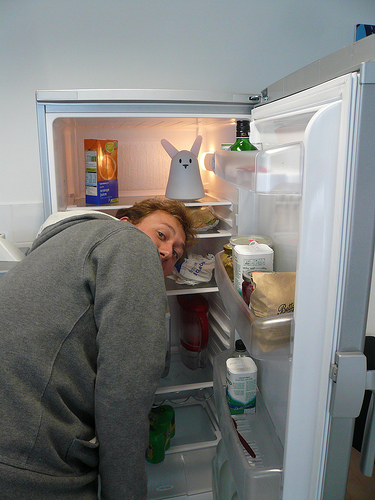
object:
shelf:
[62, 186, 234, 297]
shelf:
[138, 350, 285, 500]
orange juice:
[82, 136, 119, 205]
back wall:
[63, 124, 218, 406]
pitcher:
[172, 292, 210, 370]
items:
[215, 248, 295, 363]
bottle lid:
[236, 119, 251, 137]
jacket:
[0, 207, 172, 500]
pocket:
[66, 433, 100, 482]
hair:
[115, 194, 205, 268]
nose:
[158, 241, 173, 263]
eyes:
[154, 228, 168, 245]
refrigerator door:
[211, 30, 374, 500]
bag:
[247, 269, 296, 353]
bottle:
[228, 116, 259, 155]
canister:
[176, 293, 211, 370]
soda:
[143, 401, 178, 462]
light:
[198, 150, 215, 172]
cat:
[160, 134, 205, 200]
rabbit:
[159, 133, 205, 207]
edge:
[60, 199, 236, 301]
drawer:
[149, 382, 222, 459]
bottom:
[126, 447, 216, 499]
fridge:
[34, 35, 375, 500]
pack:
[145, 405, 175, 464]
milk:
[224, 355, 257, 421]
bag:
[167, 250, 216, 286]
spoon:
[166, 273, 191, 285]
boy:
[0, 197, 203, 500]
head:
[114, 197, 204, 280]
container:
[240, 270, 276, 306]